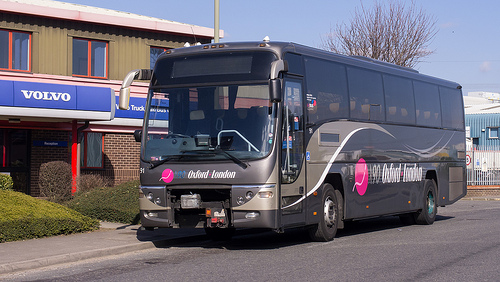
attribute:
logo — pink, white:
[339, 155, 432, 197]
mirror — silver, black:
[116, 57, 146, 121]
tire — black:
[306, 184, 349, 243]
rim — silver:
[324, 194, 337, 224]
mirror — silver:
[110, 66, 143, 114]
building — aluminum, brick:
[20, 10, 138, 187]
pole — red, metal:
[62, 134, 91, 205]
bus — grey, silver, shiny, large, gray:
[135, 42, 474, 256]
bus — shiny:
[123, 37, 479, 243]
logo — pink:
[342, 149, 377, 200]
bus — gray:
[111, 42, 451, 252]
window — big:
[436, 78, 470, 133]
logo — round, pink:
[352, 153, 373, 198]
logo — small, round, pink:
[157, 164, 173, 185]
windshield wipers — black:
[149, 148, 254, 173]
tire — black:
[308, 181, 342, 241]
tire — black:
[411, 175, 440, 221]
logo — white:
[20, 85, 76, 104]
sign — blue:
[0, 66, 116, 123]